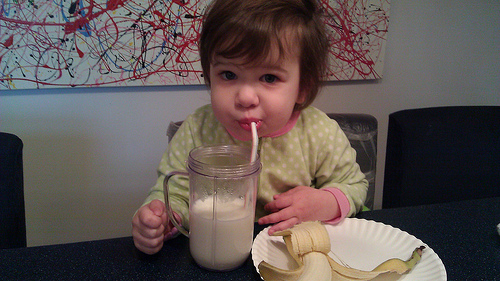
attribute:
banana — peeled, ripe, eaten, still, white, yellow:
[291, 243, 337, 278]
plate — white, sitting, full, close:
[367, 219, 396, 250]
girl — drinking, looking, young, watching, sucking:
[188, 14, 318, 167]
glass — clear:
[174, 142, 273, 256]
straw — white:
[237, 113, 274, 155]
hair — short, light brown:
[197, 14, 321, 81]